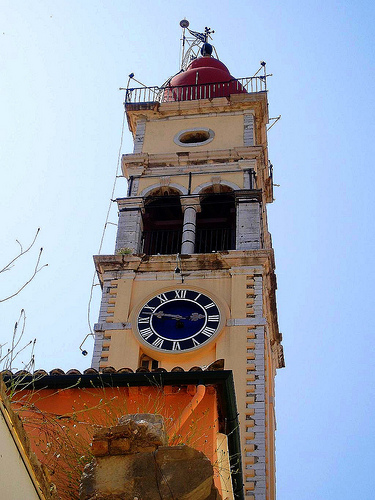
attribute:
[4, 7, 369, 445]
sky — pictured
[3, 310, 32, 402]
branches — pictured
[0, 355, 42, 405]
branches — pictured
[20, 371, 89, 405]
branches — pictured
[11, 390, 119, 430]
branches — pictured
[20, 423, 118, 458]
branches — pictured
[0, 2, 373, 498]
sky — blue, cloudless, pictured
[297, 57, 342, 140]
sky — clouds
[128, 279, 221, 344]
clock — pictured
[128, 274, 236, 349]
clock — black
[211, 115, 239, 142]
wall — brown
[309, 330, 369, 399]
clouds — white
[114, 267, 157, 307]
wall — clean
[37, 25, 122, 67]
sky — blue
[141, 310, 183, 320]
minute hand — pictured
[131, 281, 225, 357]
clock — big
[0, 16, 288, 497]
tower — blue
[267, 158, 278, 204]
pipe — drainage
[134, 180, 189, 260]
arch — open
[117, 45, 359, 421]
building — pictured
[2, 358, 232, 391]
roof — pictured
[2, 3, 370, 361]
sky — pictured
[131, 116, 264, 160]
wall — pictured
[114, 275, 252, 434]
wall — cream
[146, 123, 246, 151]
wall — cream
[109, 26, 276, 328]
tower — tall, grey, cream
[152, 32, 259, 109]
dome — red, rounded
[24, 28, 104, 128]
clouds — white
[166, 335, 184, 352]
numeral — VI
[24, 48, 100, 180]
sky — blue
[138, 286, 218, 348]
watch — blue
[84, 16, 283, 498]
tower — tall